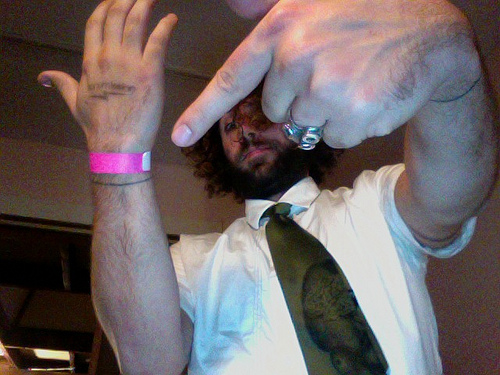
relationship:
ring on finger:
[279, 112, 326, 150] [282, 93, 333, 146]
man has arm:
[36, 1, 498, 373] [30, 0, 197, 375]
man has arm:
[36, 1, 498, 373] [384, 0, 489, 253]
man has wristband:
[36, 1, 498, 373] [85, 144, 154, 179]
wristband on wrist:
[85, 144, 154, 179] [90, 151, 158, 200]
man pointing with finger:
[36, 1, 498, 373] [167, 29, 269, 154]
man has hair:
[36, 1, 498, 373] [173, 92, 350, 195]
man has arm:
[36, 1, 498, 373] [89, 174, 194, 374]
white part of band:
[141, 150, 153, 172] [87, 147, 151, 172]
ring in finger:
[282, 107, 328, 151] [280, 85, 336, 166]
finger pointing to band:
[168, 22, 273, 151] [84, 152, 152, 174]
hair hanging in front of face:
[224, 118, 244, 151] [179, 72, 348, 192]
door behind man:
[2, 211, 179, 367] [36, 1, 498, 373]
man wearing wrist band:
[36, 0, 499, 373] [89, 145, 154, 179]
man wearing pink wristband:
[36, 1, 498, 373] [87, 150, 152, 175]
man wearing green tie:
[36, 1, 498, 373] [261, 202, 394, 374]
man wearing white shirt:
[36, 1, 498, 373] [168, 161, 474, 366]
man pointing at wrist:
[36, 1, 498, 373] [58, 116, 171, 199]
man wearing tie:
[36, 0, 499, 373] [272, 210, 387, 374]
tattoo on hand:
[79, 73, 149, 110] [28, 2, 184, 171]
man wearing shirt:
[36, 1, 498, 373] [171, 160, 474, 372]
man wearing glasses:
[36, 0, 499, 373] [218, 108, 271, 140]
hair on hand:
[413, 13, 486, 123] [172, 0, 499, 233]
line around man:
[89, 172, 151, 194] [36, 1, 498, 373]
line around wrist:
[89, 172, 151, 194] [85, 132, 151, 190]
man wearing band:
[36, 1, 498, 373] [87, 145, 152, 177]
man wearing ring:
[36, 0, 499, 373] [282, 122, 322, 152]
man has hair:
[36, 1, 498, 373] [194, 124, 332, 200]